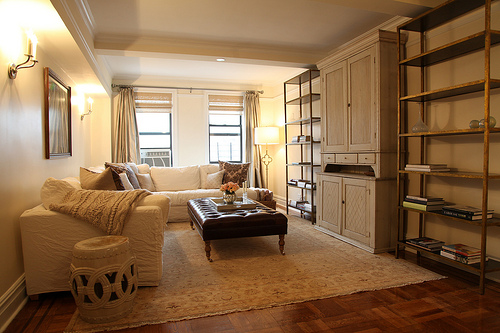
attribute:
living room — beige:
[6, 3, 498, 333]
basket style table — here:
[63, 230, 144, 323]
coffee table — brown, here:
[186, 188, 295, 264]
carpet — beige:
[70, 209, 451, 331]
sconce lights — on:
[5, 17, 104, 124]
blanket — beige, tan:
[35, 175, 162, 237]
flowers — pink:
[219, 179, 240, 195]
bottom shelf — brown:
[391, 226, 500, 285]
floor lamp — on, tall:
[246, 116, 284, 210]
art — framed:
[38, 63, 78, 167]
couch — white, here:
[99, 158, 278, 226]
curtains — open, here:
[111, 81, 274, 195]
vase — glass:
[467, 114, 497, 134]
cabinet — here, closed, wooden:
[312, 170, 399, 249]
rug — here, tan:
[67, 199, 452, 331]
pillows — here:
[74, 156, 140, 198]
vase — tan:
[220, 191, 239, 203]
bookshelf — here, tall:
[392, 2, 500, 295]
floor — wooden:
[4, 274, 492, 332]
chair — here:
[23, 183, 172, 308]